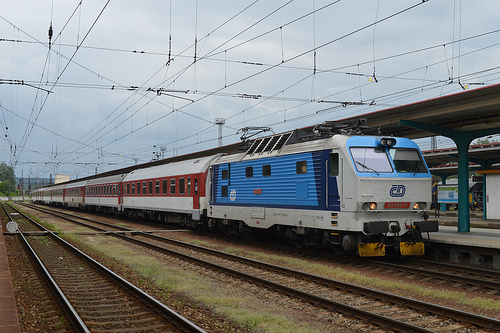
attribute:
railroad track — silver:
[3, 196, 217, 331]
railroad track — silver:
[5, 190, 498, 331]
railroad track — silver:
[375, 249, 499, 294]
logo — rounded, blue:
[390, 183, 409, 196]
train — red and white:
[11, 137, 489, 244]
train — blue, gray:
[28, 124, 436, 261]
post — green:
[444, 129, 488, 241]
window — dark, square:
[176, 177, 185, 194]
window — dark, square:
[169, 177, 176, 192]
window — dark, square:
[155, 177, 160, 192]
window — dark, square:
[141, 180, 146, 194]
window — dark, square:
[128, 182, 136, 194]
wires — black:
[0, 0, 498, 190]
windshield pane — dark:
[390, 147, 427, 176]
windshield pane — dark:
[352, 146, 392, 172]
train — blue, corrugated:
[83, 80, 498, 275]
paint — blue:
[210, 164, 337, 210]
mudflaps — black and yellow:
[348, 236, 438, 266]